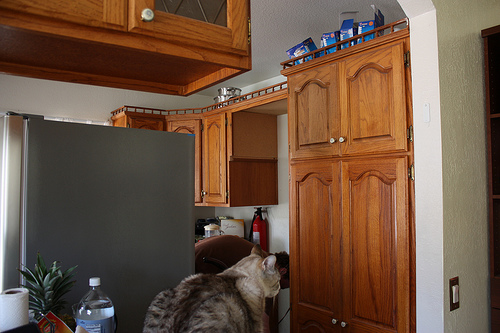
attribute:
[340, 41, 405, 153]
door — brown, wooden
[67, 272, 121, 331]
bottle — clear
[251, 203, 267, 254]
extinguisher — red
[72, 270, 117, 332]
bottle — water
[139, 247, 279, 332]
cat — grey, large, gray, black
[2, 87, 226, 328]
refrigerator — grey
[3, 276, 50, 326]
roll — white, paper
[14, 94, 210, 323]
refrigerator — large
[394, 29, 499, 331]
wall — white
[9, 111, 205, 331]
refrigerator — gray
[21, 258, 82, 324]
plant — potted, thick leaved, green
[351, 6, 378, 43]
box — opened, blue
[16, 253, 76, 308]
plant — green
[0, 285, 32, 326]
paper towel — white, roll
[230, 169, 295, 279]
extinguisher — red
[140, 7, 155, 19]
knob — white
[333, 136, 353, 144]
knob — white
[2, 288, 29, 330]
roll — paper towels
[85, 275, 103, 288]
top — white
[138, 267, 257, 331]
body — black, brown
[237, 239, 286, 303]
head — grey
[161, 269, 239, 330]
back fur — dark grey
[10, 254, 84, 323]
fronds — green pineapple